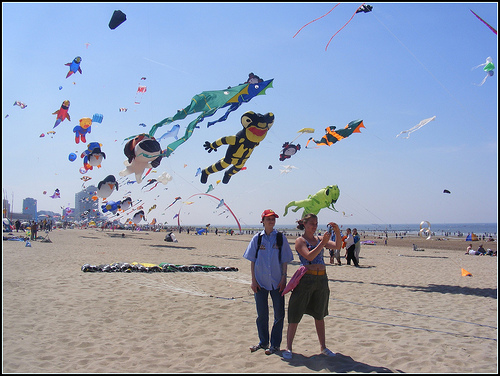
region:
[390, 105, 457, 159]
Small kite in the blue sky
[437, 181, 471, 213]
Small kite in the blue sky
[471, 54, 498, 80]
Small kite in the blue sky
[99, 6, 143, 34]
Small kite in the blue sky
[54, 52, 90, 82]
Small kite in the blue sky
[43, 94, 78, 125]
Small kite in the blue sky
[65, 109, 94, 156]
Small kite in the blue sky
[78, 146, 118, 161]
Small kite in the blue sky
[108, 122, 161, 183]
Small kite in the blue sky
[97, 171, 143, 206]
Small kite in the blue sky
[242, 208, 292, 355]
woman in jeans and red hat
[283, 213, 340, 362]
woman in white shoes and green skirt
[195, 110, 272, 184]
yellow and black flying kite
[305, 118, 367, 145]
orange and blue flying kite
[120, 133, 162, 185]
black and white flying kite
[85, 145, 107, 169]
black and white flying kite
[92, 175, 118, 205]
black and white flying kite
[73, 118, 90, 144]
red, blue, and yellow flying kite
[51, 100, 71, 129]
red and blue flying kite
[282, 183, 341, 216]
green cricket flying kite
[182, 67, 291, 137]
kite flying in the sky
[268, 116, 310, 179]
kite flying in the sky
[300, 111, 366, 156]
kite flying in the sky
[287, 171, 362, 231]
kite flying in the sky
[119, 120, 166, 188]
kite flying in the sky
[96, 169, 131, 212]
kite flying in the sky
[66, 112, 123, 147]
kite flying in the sky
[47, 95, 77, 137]
kite flying in the sky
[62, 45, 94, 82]
kite flying in the sky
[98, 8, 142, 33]
kite flying in the sky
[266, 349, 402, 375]
A shadow on the ground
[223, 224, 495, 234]
Water at the beach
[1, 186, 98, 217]
Buildings in the distance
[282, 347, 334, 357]
The woman is wearing white shoes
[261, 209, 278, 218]
The man is wearing a hat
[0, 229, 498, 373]
Sand beneath the kites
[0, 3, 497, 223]
The sky above the kites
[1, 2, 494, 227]
Kites in the air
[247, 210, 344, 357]
Two people standing below the kites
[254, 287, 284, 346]
The man is wearing pants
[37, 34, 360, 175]
Several kites flying in the sky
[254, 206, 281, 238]
Orange baseball hat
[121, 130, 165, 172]
White, black and brown dog kite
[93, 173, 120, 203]
Black and white penguin kite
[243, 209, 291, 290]
Man wearing a blue shirt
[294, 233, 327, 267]
Lady wearing sleeveless blue shirt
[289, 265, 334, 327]
Lady wearing long green shorts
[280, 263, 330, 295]
Pink scarf tied onto green shorts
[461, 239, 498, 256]
People sitting in the sand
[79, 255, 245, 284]
Large kite laying in the sand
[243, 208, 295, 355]
Person wearing red hat